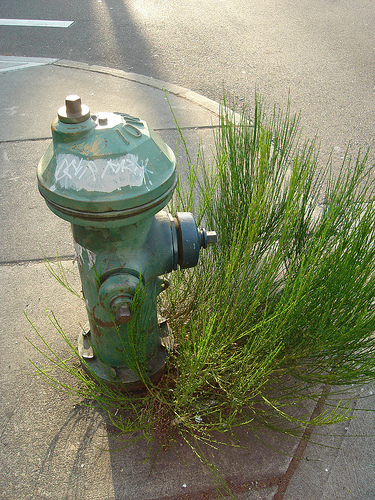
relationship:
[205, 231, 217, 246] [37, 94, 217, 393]
screw on fire hydrant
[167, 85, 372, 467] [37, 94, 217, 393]
grass by fire hydrant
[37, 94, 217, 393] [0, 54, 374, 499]
fire hydrant on sidewalk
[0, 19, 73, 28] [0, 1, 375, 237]
line on street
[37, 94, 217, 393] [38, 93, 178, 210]
fire hydrant has top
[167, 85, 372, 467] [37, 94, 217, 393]
grass beside fire hydrant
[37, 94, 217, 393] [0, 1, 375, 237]
fire hydrant beside street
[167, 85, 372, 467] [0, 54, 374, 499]
grass on sidewalk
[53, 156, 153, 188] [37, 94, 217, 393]
graffiti on fire hydrant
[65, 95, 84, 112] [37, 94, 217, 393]
bolt on fire hydrant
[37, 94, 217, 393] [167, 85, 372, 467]
fire hydrant next to grass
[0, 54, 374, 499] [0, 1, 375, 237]
sidewalk next to street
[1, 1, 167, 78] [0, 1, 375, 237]
shadow on street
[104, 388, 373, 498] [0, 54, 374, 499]
shadow on sidewalk